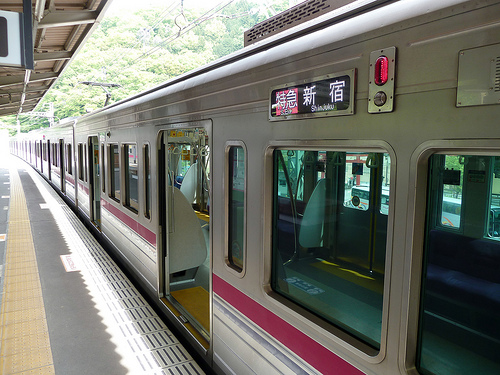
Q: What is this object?
A: Train.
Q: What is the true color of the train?
A: Silver.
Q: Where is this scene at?
A: A station.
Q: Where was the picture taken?
A: At a train station.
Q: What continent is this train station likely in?
A: Asia.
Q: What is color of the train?
A: Gray.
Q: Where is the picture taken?
A: A train station.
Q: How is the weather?
A: Sunny.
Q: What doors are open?
A: Train doors.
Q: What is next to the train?
A: A platform.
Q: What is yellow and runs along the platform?
A: A stripe.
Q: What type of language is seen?
A: Asian.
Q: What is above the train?
A: Trees.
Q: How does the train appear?
A: Empty.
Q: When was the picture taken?
A: Afternoon.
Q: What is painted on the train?
A: Red stripe.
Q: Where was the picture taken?
A: At the train station.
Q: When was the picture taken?
A: During the daytime.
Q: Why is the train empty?
A: Passengers got off.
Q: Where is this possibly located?
A: In Korea.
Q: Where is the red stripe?
A: On the side of the train.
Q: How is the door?
A: Open.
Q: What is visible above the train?
A: Trees.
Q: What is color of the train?
A: Silver.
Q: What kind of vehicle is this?
A: Train.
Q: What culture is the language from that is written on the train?
A: Asian culture.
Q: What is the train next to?
A: Platform.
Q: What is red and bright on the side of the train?
A: Side train light.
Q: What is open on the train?
A: Door.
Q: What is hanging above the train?
A: Power lines.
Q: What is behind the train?
A: Trees.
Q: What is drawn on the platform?
A: Yellow line.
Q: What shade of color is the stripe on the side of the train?
A: Red.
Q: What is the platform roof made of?
A: Wood.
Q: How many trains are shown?
A: One.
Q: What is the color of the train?
A: Silver.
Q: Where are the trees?
A: Behind train.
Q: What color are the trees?
A: Green.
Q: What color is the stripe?
A: Red.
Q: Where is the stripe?
A: On train.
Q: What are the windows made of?
A: Glass.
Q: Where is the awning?
A: Above platform.